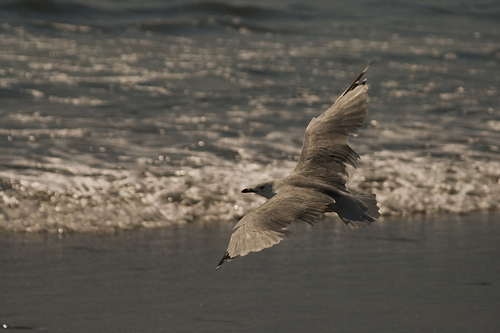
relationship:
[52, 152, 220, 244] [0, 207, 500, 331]
water rolling rolling on beach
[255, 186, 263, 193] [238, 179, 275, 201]
eye on side of head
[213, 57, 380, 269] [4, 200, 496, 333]
bird over water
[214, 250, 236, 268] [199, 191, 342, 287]
tip of wing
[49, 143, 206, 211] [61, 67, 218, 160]
ripples on water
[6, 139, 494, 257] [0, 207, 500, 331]
wave on beach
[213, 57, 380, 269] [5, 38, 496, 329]
bird in air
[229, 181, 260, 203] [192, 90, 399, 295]
beak of bird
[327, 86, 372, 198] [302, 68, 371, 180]
feathers on wing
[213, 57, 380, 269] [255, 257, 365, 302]
bird flying at beach